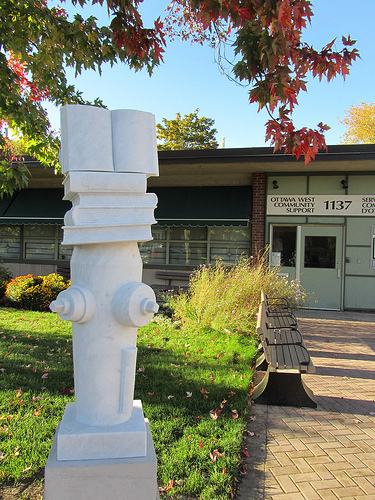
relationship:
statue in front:
[38, 101, 158, 490] [9, 284, 372, 499]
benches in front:
[255, 295, 312, 407] [9, 284, 372, 499]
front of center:
[9, 284, 372, 499] [2, 157, 372, 312]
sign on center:
[268, 195, 374, 215] [2, 157, 372, 312]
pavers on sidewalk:
[266, 410, 373, 496] [266, 308, 370, 498]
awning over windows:
[8, 186, 250, 225] [2, 226, 249, 268]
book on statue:
[60, 106, 162, 177] [38, 101, 158, 490]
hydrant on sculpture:
[51, 245, 154, 423] [38, 101, 158, 490]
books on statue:
[62, 172, 159, 243] [38, 101, 158, 490]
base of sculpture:
[47, 402, 158, 499] [38, 101, 158, 490]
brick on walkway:
[266, 410, 373, 496] [266, 308, 370, 498]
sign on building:
[268, 195, 374, 215] [2, 157, 372, 312]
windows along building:
[2, 226, 249, 268] [2, 157, 372, 312]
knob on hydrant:
[138, 299, 161, 319] [51, 245, 154, 423]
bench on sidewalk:
[255, 295, 312, 407] [266, 308, 370, 498]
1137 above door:
[326, 201, 351, 211] [298, 223, 344, 313]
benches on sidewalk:
[255, 295, 312, 407] [266, 308, 370, 498]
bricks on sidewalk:
[266, 410, 373, 496] [266, 308, 370, 498]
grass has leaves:
[8, 308, 253, 492] [27, 331, 73, 399]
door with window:
[298, 223, 344, 313] [304, 235, 337, 269]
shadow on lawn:
[5, 329, 248, 419] [8, 308, 253, 492]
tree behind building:
[160, 113, 220, 152] [2, 157, 372, 312]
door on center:
[298, 223, 344, 313] [2, 157, 372, 312]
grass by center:
[8, 308, 253, 492] [2, 157, 372, 312]